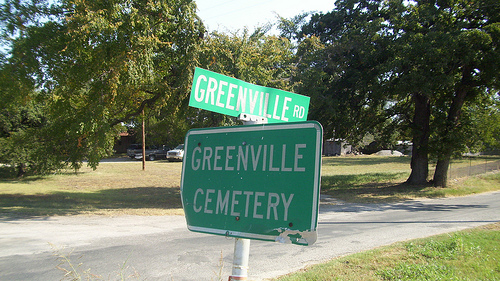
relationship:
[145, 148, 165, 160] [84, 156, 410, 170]
car on street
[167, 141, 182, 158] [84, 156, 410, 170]
car on street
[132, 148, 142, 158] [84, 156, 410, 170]
car on street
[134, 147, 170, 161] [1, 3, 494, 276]
car on street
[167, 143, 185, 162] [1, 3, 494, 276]
car on street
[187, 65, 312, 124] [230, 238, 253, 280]
sign on pole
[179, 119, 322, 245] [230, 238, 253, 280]
sign on pole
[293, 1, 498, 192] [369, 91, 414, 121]
tall tree with branch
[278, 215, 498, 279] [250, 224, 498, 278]
grassy on sidewalk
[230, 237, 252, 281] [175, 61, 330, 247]
pole holds signs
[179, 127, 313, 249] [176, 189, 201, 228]
sign bent in corner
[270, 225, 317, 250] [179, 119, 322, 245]
paint chipped on sign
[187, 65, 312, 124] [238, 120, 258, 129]
sign on pole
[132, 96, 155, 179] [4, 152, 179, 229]
pole in middle of lawn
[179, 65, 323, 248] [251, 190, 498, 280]
boards in road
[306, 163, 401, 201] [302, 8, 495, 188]
shadow of trees